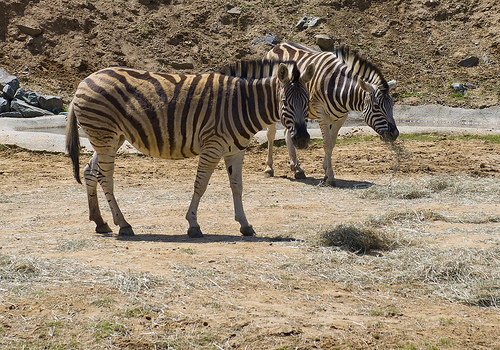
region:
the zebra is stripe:
[63, 44, 317, 261]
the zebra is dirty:
[69, 61, 314, 236]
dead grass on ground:
[316, 221, 403, 272]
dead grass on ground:
[422, 236, 484, 314]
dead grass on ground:
[113, 264, 166, 323]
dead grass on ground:
[16, 254, 63, 277]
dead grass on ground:
[57, 231, 90, 251]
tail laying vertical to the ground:
[56, 63, 143, 251]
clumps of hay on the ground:
[272, 205, 484, 315]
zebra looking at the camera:
[267, 53, 329, 165]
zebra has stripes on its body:
[45, 57, 317, 249]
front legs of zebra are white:
[311, 121, 363, 206]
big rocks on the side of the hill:
[190, 8, 495, 115]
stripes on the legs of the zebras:
[61, 142, 279, 249]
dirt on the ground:
[6, 151, 487, 341]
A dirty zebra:
[57, 63, 317, 247]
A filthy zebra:
[61, 57, 316, 243]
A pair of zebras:
[53, 31, 413, 239]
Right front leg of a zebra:
[180, 143, 219, 239]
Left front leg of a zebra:
[221, 145, 261, 240]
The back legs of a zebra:
[75, 135, 138, 244]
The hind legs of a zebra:
[78, 138, 138, 240]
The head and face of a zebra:
[265, 58, 321, 153]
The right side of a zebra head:
[355, 60, 411, 148]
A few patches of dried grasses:
[312, 210, 479, 302]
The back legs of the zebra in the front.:
[83, 140, 131, 235]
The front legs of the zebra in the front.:
[182, 144, 257, 241]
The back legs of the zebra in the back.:
[265, 130, 300, 177]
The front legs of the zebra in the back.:
[319, 112, 343, 190]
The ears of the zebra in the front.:
[275, 67, 320, 81]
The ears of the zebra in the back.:
[355, 79, 402, 91]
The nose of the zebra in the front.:
[290, 132, 310, 147]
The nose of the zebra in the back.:
[380, 128, 399, 139]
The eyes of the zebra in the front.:
[277, 99, 309, 107]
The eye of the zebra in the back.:
[367, 100, 381, 110]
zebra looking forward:
[64, 58, 317, 236]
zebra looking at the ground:
[264, 41, 399, 187]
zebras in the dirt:
[64, 38, 399, 236]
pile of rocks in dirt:
[0, 66, 62, 119]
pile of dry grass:
[304, 206, 499, 307]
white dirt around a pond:
[0, 101, 499, 154]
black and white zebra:
[66, 58, 316, 238]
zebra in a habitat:
[64, 58, 315, 238]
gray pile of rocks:
[0, 68, 63, 122]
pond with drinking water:
[397, 98, 499, 135]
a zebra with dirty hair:
[62, 54, 321, 239]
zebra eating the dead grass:
[316, 46, 428, 174]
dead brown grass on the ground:
[300, 218, 406, 284]